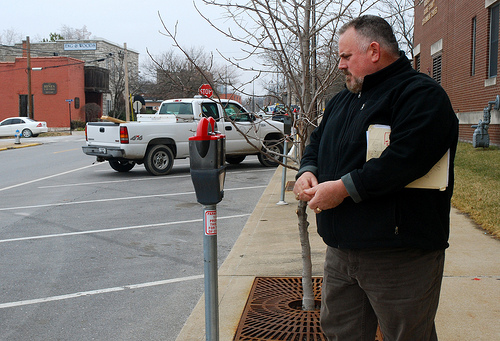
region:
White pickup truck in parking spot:
[92, 95, 292, 163]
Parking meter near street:
[186, 113, 227, 339]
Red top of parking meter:
[192, 112, 225, 138]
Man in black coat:
[291, 16, 445, 339]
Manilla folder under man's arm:
[363, 115, 450, 192]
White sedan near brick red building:
[2, 117, 52, 135]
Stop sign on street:
[194, 80, 211, 95]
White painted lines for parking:
[2, 159, 227, 339]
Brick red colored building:
[2, 56, 86, 131]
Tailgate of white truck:
[82, 125, 129, 145]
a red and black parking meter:
[185, 113, 226, 204]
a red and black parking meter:
[281, 109, 293, 134]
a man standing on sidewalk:
[300, 14, 458, 339]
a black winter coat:
[298, 55, 458, 253]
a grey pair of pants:
[319, 244, 443, 339]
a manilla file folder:
[364, 124, 451, 191]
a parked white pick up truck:
[83, 94, 294, 176]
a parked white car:
[0, 115, 50, 137]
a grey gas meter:
[471, 99, 499, 150]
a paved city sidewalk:
[179, 127, 498, 339]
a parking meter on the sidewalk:
[187, 116, 227, 333]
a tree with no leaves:
[217, 0, 315, 301]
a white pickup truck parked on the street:
[82, 98, 279, 165]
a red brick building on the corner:
[1, 52, 87, 122]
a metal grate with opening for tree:
[242, 273, 326, 340]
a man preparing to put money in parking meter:
[292, 14, 456, 339]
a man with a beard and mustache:
[325, 12, 401, 95]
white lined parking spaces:
[8, 188, 206, 336]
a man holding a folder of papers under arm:
[327, 15, 442, 263]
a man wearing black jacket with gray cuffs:
[335, 173, 395, 211]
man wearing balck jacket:
[296, 13, 461, 263]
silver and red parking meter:
[187, 115, 229, 338]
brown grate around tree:
[230, 268, 345, 339]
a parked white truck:
[82, 93, 291, 174]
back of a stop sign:
[130, 96, 142, 116]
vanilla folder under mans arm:
[359, 115, 454, 192]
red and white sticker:
[201, 204, 220, 239]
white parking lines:
[2, 163, 278, 325]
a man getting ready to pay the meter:
[170, 13, 465, 340]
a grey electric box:
[468, 88, 498, 157]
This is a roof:
[4, 9, 144, 61]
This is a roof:
[7, 46, 101, 96]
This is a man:
[295, 15, 465, 339]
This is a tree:
[291, 13, 340, 194]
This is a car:
[74, 91, 299, 181]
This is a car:
[1, 105, 55, 147]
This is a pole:
[187, 108, 248, 330]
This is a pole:
[14, 33, 46, 133]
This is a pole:
[118, 35, 145, 137]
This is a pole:
[278, 162, 324, 328]